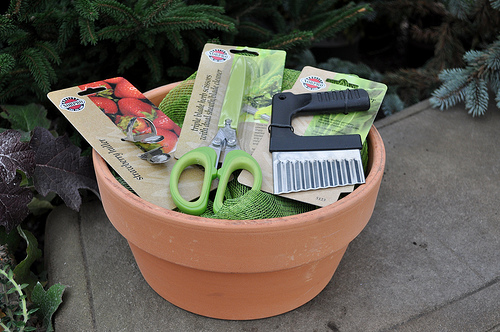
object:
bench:
[44, 82, 499, 331]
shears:
[168, 53, 261, 218]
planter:
[33, 43, 387, 323]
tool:
[265, 87, 371, 197]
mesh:
[252, 204, 279, 217]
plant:
[26, 125, 92, 212]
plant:
[29, 281, 67, 332]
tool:
[119, 114, 171, 165]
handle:
[265, 88, 370, 154]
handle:
[166, 146, 262, 218]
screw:
[212, 138, 221, 147]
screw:
[226, 137, 236, 147]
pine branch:
[461, 77, 489, 116]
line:
[32, 161, 65, 173]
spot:
[404, 234, 433, 253]